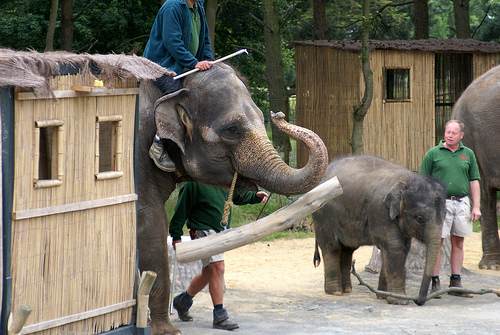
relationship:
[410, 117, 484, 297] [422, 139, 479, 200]
man with shirt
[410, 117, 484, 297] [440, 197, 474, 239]
man wearing shorts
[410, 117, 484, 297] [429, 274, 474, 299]
man wearing boots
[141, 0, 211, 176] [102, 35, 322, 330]
man on elephant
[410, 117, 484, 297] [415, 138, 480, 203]
man in shirt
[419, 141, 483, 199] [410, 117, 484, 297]
shirt on man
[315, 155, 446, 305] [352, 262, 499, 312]
baby elephant with stick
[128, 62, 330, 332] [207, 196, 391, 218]
elephant carrying log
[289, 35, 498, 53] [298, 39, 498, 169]
roof on building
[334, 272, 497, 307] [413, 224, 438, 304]
limb in trunk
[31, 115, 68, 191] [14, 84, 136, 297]
window on shack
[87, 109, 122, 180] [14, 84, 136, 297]
window on shack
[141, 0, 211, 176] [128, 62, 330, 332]
man on elephant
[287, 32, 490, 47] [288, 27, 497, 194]
roof on building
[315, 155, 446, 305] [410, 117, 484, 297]
baby elephant next to man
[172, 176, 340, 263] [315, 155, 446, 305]
log carried by baby elephant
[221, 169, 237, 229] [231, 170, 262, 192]
rope in mouth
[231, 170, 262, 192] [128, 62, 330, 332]
mouth of elephant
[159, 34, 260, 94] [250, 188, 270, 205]
stick in man's hand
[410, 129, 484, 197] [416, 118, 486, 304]
shirt on man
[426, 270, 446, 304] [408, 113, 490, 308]
shoe on man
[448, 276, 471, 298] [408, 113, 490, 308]
boots on man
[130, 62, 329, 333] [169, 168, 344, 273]
elephant carrying sticks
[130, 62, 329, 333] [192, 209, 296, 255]
elephant carrying log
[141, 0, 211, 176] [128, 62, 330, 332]
man riding elephant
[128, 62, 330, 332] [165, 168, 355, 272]
elephant carrying log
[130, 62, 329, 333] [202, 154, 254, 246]
elephant carrying stick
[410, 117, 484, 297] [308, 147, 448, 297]
man standing next to small elephant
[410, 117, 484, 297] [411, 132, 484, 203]
man wearing shirt